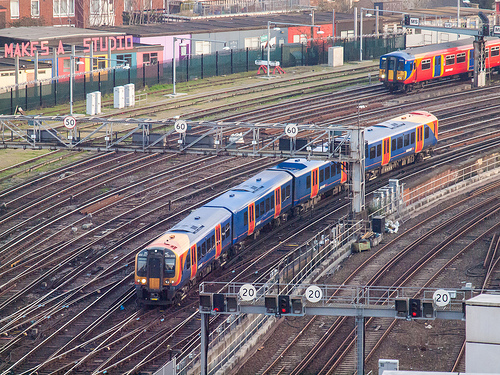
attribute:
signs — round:
[228, 275, 470, 321]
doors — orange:
[209, 219, 239, 257]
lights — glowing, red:
[230, 284, 432, 322]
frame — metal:
[29, 118, 385, 251]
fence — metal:
[6, 49, 391, 160]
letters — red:
[7, 35, 132, 85]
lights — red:
[203, 283, 472, 323]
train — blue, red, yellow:
[151, 145, 348, 295]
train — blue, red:
[162, 123, 438, 316]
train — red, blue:
[146, 112, 426, 312]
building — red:
[283, 26, 333, 57]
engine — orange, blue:
[113, 183, 263, 322]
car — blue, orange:
[216, 161, 289, 251]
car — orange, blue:
[268, 138, 347, 214]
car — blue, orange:
[345, 96, 445, 183]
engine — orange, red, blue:
[383, 23, 496, 82]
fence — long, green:
[173, 34, 395, 96]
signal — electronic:
[47, 115, 334, 167]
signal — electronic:
[263, 277, 304, 330]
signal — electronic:
[385, 299, 445, 326]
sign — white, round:
[235, 280, 255, 304]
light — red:
[272, 301, 290, 312]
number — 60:
[173, 119, 190, 135]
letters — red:
[4, 39, 65, 61]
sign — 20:
[304, 283, 324, 306]